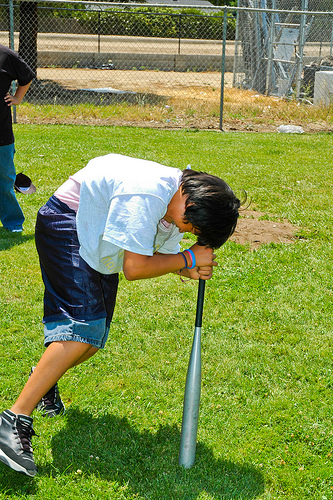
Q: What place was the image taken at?
A: It was taken at the field.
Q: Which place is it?
A: It is a field.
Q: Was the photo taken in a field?
A: Yes, it was taken in a field.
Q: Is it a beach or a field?
A: It is a field.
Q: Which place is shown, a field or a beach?
A: It is a field.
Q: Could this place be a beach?
A: No, it is a field.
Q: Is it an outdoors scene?
A: Yes, it is outdoors.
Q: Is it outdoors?
A: Yes, it is outdoors.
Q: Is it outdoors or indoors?
A: It is outdoors.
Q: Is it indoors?
A: No, it is outdoors.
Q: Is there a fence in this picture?
A: Yes, there is a fence.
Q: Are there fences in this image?
A: Yes, there is a fence.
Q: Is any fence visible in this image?
A: Yes, there is a fence.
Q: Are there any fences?
A: Yes, there is a fence.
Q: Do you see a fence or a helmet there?
A: Yes, there is a fence.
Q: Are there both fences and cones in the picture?
A: No, there is a fence but no cones.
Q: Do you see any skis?
A: No, there are no skis.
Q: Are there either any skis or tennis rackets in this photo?
A: No, there are no skis or tennis rackets.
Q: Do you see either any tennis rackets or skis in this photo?
A: No, there are no skis or tennis rackets.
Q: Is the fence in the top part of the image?
A: Yes, the fence is in the top of the image.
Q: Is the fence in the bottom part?
A: No, the fence is in the top of the image.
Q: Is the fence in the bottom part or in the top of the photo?
A: The fence is in the top of the image.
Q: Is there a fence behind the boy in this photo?
A: Yes, there is a fence behind the boy.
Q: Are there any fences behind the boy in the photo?
A: Yes, there is a fence behind the boy.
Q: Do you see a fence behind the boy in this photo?
A: Yes, there is a fence behind the boy.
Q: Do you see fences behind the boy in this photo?
A: Yes, there is a fence behind the boy.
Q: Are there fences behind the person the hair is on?
A: Yes, there is a fence behind the boy.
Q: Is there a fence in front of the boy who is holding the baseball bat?
A: No, the fence is behind the boy.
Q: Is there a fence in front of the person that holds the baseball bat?
A: No, the fence is behind the boy.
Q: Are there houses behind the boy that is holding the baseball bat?
A: No, there is a fence behind the boy.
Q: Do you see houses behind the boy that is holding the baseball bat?
A: No, there is a fence behind the boy.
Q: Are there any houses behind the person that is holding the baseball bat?
A: No, there is a fence behind the boy.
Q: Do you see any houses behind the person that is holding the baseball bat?
A: No, there is a fence behind the boy.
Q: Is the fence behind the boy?
A: Yes, the fence is behind the boy.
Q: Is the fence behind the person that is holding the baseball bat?
A: Yes, the fence is behind the boy.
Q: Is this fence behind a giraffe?
A: No, the fence is behind the boy.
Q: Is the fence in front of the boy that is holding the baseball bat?
A: No, the fence is behind the boy.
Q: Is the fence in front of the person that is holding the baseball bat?
A: No, the fence is behind the boy.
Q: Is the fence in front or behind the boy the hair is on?
A: The fence is behind the boy.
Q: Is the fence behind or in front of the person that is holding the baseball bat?
A: The fence is behind the boy.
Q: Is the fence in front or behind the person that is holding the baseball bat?
A: The fence is behind the boy.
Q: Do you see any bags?
A: No, there are no bags.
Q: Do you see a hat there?
A: Yes, there is a hat.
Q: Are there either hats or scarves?
A: Yes, there is a hat.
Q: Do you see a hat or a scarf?
A: Yes, there is a hat.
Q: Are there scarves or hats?
A: Yes, there is a hat.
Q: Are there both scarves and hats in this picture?
A: No, there is a hat but no scarves.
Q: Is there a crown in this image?
A: No, there are no crowns.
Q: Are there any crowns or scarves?
A: No, there are no crowns or scarves.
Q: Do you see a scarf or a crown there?
A: No, there are no crowns or scarves.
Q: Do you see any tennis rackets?
A: No, there are no tennis rackets.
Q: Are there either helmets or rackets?
A: No, there are no rackets or helmets.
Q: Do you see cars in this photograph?
A: No, there are no cars.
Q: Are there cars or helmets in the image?
A: No, there are no cars or helmets.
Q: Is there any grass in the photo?
A: Yes, there is grass.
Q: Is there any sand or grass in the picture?
A: Yes, there is grass.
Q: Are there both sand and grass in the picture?
A: No, there is grass but no sand.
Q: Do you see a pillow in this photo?
A: No, there are no pillows.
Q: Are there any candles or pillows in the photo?
A: No, there are no pillows or candles.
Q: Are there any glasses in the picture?
A: No, there are no glasses.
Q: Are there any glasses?
A: No, there are no glasses.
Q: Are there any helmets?
A: No, there are no helmets.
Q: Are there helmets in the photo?
A: No, there are no helmets.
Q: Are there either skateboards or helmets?
A: No, there are no helmets or skateboards.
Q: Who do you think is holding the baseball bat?
A: The boy is holding the baseball bat.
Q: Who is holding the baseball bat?
A: The boy is holding the baseball bat.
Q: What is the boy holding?
A: The boy is holding the baseball bat.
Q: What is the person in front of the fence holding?
A: The boy is holding the baseball bat.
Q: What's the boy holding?
A: The boy is holding the baseball bat.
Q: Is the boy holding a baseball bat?
A: Yes, the boy is holding a baseball bat.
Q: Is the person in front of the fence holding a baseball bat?
A: Yes, the boy is holding a baseball bat.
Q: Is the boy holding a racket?
A: No, the boy is holding a baseball bat.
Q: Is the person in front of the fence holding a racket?
A: No, the boy is holding a baseball bat.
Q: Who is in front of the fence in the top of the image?
A: The boy is in front of the fence.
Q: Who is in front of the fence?
A: The boy is in front of the fence.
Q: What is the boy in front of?
A: The boy is in front of the fence.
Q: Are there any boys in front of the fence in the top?
A: Yes, there is a boy in front of the fence.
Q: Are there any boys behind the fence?
A: No, the boy is in front of the fence.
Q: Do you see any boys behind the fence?
A: No, the boy is in front of the fence.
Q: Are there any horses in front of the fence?
A: No, there is a boy in front of the fence.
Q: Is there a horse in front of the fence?
A: No, there is a boy in front of the fence.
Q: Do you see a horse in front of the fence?
A: No, there is a boy in front of the fence.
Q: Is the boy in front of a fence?
A: Yes, the boy is in front of a fence.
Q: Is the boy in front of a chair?
A: No, the boy is in front of a fence.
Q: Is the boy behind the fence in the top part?
A: No, the boy is in front of the fence.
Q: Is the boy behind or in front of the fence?
A: The boy is in front of the fence.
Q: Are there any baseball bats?
A: Yes, there is a baseball bat.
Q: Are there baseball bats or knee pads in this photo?
A: Yes, there is a baseball bat.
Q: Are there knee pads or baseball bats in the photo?
A: Yes, there is a baseball bat.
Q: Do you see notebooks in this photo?
A: No, there are no notebooks.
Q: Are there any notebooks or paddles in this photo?
A: No, there are no notebooks or paddles.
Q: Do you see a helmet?
A: No, there are no helmets.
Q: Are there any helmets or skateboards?
A: No, there are no helmets or skateboards.